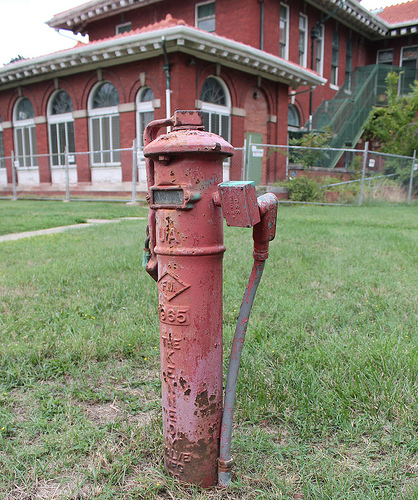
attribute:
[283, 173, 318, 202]
bush — small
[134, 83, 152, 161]
window — large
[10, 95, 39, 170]
window — large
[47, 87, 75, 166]
window — large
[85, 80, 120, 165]
window — large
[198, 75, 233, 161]
window — large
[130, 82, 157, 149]
window — large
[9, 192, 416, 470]
field — large, green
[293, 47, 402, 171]
staircase — green 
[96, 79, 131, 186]
window — large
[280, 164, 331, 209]
bush — green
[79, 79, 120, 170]
window — large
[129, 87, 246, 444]
hydrant — grey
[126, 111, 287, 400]
hydrant — red 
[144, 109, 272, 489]
hydrant — rusted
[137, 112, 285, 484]
hydrant — red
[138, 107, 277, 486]
fire hydrant — rusty 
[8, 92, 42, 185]
window — large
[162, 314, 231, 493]
paint — chipping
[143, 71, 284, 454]
pipe — metal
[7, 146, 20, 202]
pole — silver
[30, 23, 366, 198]
building — brick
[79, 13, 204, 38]
shingles — red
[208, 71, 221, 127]
window — large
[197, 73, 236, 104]
windows — arched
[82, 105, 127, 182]
windows — narrow, long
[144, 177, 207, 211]
panel — metal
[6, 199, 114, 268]
walkway — cement, narrow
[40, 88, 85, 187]
window — large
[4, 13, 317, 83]
roof — white, decorative